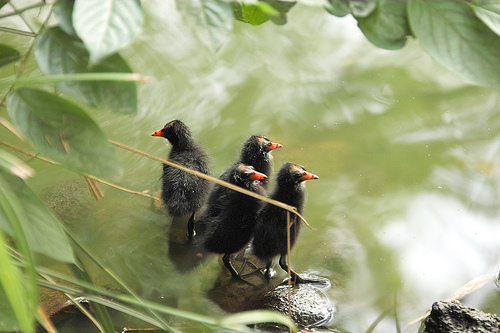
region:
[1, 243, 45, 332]
leaf on a plant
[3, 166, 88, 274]
leaf on a plant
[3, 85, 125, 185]
leaf on a plant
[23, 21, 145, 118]
leaf on a plant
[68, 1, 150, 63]
leaf on a plant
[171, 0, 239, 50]
leaf on a plant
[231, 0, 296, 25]
leaf on a plant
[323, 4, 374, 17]
leaf on a plant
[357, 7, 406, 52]
leaf on a plant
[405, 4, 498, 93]
leaf on a plant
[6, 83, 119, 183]
green leaf on tree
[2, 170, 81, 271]
green leaf on tree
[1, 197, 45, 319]
green leaf on tree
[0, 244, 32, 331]
green leaf on tree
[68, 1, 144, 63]
green leaf on tree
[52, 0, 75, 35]
green leaf on tree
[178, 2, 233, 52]
green leaf on tree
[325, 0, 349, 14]
green leaf on tree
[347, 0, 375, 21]
green leaf on tree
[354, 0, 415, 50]
green leaf on tree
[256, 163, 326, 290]
small black colored bird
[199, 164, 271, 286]
small black colored bird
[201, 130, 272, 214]
small black colored bird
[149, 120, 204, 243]
small black colored bird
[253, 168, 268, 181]
small orange bird beak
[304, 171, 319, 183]
small orange bird beak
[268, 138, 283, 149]
small orange bird beak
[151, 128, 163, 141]
small orange bird beak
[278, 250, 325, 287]
small black bird foot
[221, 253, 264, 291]
small black bird foot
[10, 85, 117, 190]
green leaf on plant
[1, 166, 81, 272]
green leaf on plant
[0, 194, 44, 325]
green leaf on plant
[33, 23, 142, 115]
green leaf on plant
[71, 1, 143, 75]
green leaf on plant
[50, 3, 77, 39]
green leaf on plant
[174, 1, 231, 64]
green leaf on plant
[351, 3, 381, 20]
green leaf on plant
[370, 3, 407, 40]
green leaf on plant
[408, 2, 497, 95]
green leaf on plant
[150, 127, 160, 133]
The beak of the bird on the left.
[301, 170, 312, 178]
The beak of the bird on the far right.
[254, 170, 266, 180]
The beak of the bird in the middle.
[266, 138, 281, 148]
The beak of the bird in the back.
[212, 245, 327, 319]
The rock the birds are standing on.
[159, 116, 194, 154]
The head of the bird on the left.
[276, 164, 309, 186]
The head of the bird on the far right.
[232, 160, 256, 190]
The head of the bird in the middle.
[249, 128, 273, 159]
The head of the bird in the back.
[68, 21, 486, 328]
The water surrounding the birds.